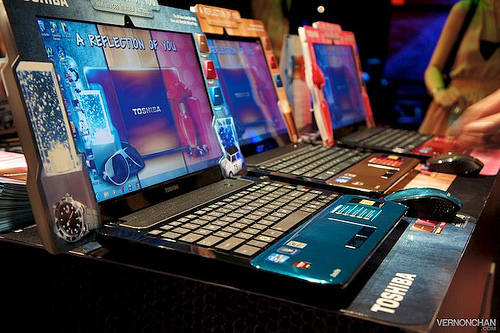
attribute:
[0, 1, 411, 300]
laptop — toshiba, three, black, blue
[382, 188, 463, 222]
mouse — black, blue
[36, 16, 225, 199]
screen — colorful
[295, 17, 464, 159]
computer — red, orange, toshiba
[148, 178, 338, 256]
keyboard — black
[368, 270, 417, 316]
logo — toshiba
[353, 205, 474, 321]
pad — mouse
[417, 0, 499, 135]
lady — standing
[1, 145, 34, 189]
paper — stacked